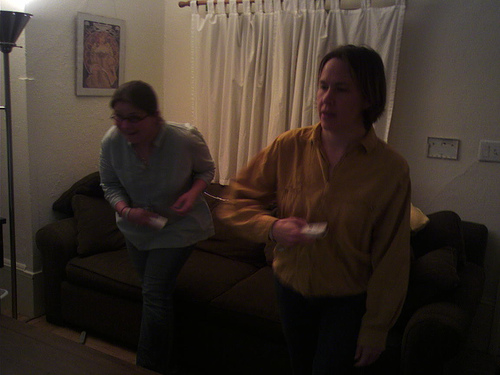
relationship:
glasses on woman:
[103, 104, 168, 130] [98, 78, 217, 372]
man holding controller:
[216, 36, 436, 373] [271, 214, 336, 254]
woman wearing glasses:
[98, 78, 217, 372] [108, 109, 153, 124]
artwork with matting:
[80, 21, 120, 88] [75, 10, 126, 99]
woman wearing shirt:
[98, 78, 217, 372] [84, 113, 230, 242]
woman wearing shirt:
[211, 41, 412, 372] [210, 123, 410, 350]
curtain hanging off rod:
[189, 1, 407, 186] [176, 0, 299, 6]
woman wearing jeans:
[98, 78, 217, 372] [121, 237, 194, 373]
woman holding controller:
[98, 78, 217, 372] [134, 205, 174, 227]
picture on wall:
[52, 9, 152, 112] [26, 2, 163, 318]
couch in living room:
[30, 136, 498, 343] [0, 3, 499, 373]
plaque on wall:
[422, 133, 461, 163] [161, 0, 498, 353]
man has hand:
[216, 45, 411, 373] [266, 215, 306, 246]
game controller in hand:
[297, 219, 330, 239] [266, 215, 306, 246]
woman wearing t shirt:
[98, 78, 217, 372] [97, 120, 217, 254]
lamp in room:
[0, 9, 34, 319] [0, 2, 499, 372]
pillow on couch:
[406, 241, 461, 300] [30, 136, 498, 343]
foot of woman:
[134, 222, 184, 362] [67, 50, 245, 372]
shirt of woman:
[84, 113, 230, 242] [77, 86, 227, 370]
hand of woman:
[179, 125, 222, 231] [98, 78, 217, 372]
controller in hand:
[124, 201, 204, 247] [167, 192, 195, 215]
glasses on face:
[108, 111, 151, 123] [95, 66, 175, 153]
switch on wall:
[411, 134, 484, 236] [396, 27, 483, 371]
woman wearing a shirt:
[98, 78, 217, 372] [84, 113, 230, 242]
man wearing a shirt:
[216, 36, 436, 373] [216, 103, 436, 322]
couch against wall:
[30, 136, 498, 343] [30, 8, 493, 284]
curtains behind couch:
[179, 0, 411, 207] [52, 148, 484, 371]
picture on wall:
[52, 9, 152, 112] [30, 8, 493, 284]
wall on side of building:
[18, 30, 169, 275] [20, 5, 488, 292]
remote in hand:
[245, 204, 357, 277] [272, 205, 311, 254]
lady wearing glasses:
[39, 71, 251, 372] [83, 100, 175, 130]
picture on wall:
[52, 9, 152, 112] [18, 30, 169, 275]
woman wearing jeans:
[98, 78, 217, 372] [126, 240, 193, 367]